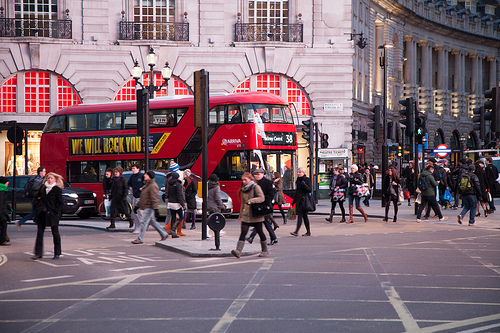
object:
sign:
[72, 133, 168, 155]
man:
[416, 165, 448, 223]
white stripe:
[383, 280, 423, 332]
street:
[0, 184, 500, 331]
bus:
[40, 92, 300, 218]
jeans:
[135, 209, 168, 243]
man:
[129, 170, 170, 244]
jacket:
[134, 179, 161, 209]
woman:
[289, 167, 317, 238]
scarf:
[241, 181, 257, 193]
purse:
[249, 203, 272, 218]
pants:
[35, 217, 63, 257]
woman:
[108, 166, 134, 230]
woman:
[346, 163, 371, 224]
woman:
[324, 167, 348, 224]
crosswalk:
[0, 221, 500, 332]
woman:
[232, 172, 270, 260]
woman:
[30, 170, 66, 259]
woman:
[382, 165, 404, 222]